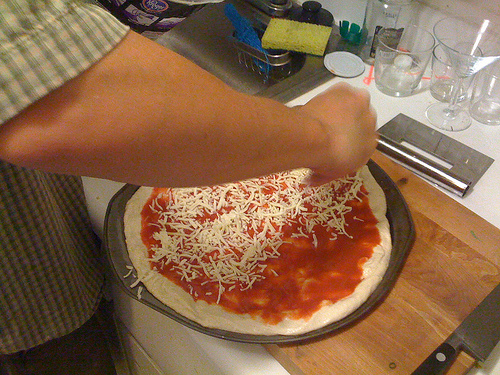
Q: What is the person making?
A: Pizza.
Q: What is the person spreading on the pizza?
A: Cheese.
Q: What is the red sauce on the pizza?
A: Tomato sauce.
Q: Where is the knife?
A: On the right side of the cutting board.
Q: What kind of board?
A: Wood.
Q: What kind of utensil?
A: Knife.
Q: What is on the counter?
A: Glasses.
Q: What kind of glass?
A: Martini.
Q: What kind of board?
A: Wood.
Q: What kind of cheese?
A: Srpinkled.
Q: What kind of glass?
A: Martini.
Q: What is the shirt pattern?
A: Checkered.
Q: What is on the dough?
A: Cheese.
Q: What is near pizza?
A: Pizza dough cutter.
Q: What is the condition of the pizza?
A: Not cooked.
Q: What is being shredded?
A: Mozzarella.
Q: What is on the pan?
A: Pizza.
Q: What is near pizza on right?
A: Knife.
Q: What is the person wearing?
A: Plaid shirt.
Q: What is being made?
A: Pizza.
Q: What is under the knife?
A: Cutting board.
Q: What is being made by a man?
A: Pizza.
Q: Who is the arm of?
A: A man.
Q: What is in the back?
A: Martini glass.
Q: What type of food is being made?
A: Pizza.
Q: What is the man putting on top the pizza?
A: Cheese.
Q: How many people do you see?
A: 1.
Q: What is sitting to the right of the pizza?
A: A knife.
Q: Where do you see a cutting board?
A: Under the pizza.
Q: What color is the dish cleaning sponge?
A: Yellow.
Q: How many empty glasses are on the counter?
A: 5.